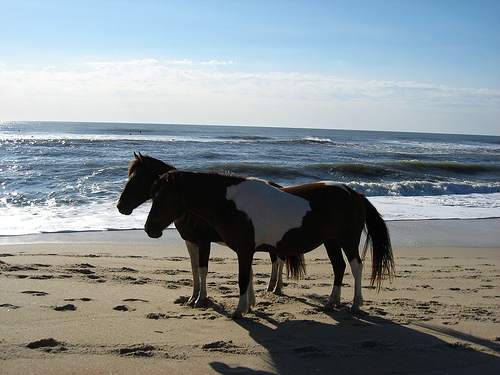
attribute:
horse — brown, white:
[144, 169, 397, 316]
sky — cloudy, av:
[132, 43, 169, 66]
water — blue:
[20, 134, 57, 157]